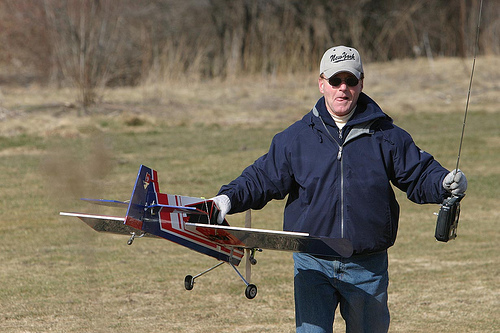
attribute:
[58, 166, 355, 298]
airplane — remote controlled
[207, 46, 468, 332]
man — blue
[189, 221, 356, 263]
wing — right wing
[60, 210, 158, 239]
wing — left wing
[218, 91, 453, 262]
jacket — blue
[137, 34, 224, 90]
plants — brown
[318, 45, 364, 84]
hat — gray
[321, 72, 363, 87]
sunglasses — dark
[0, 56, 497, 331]
field — grass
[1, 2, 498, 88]
bushes — brown